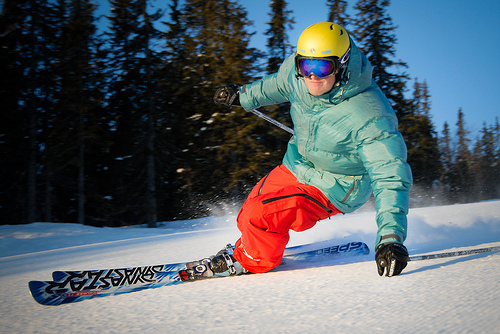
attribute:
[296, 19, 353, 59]
helmet — yellow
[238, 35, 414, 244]
blue jacket — light blue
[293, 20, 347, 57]
helmet — yellow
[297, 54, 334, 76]
goggles — blue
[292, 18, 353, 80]
helmet — yellow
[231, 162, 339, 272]
pants — orange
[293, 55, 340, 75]
goggles — reflective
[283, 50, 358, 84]
goggles — reflective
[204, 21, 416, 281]
person — skiing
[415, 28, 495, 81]
sky — blue, winter sky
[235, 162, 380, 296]
stripes — black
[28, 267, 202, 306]
skis — pair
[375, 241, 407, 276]
glove — black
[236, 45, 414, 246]
coat — puffy